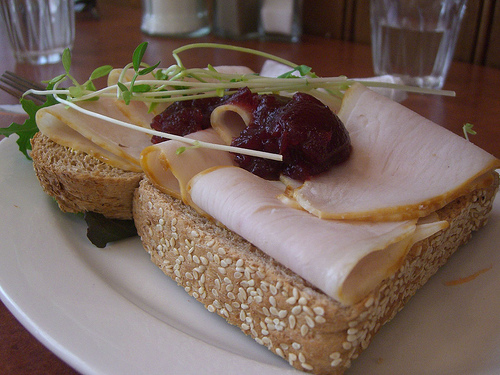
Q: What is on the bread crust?
A: Sesame seeds.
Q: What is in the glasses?
A: Water.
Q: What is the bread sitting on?
A: White plate.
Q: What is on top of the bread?
A: Lunch meat.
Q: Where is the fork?
A: Behind the plate.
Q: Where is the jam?
A: On top of lunch meat.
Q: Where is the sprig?
A: On top of jam.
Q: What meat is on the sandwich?
A: Turkey.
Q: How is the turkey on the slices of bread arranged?
A: Folded.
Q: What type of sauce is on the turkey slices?
A: Cranberry.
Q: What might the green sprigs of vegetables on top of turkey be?
A: Watercrest.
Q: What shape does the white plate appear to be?
A: Oval.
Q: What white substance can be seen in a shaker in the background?
A: Salt.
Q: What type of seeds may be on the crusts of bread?
A: Sesame.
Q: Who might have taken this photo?
A: Food photographer.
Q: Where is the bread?
A: Underneath the meat.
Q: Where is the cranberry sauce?
A: On top of the lunchmeat.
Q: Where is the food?
A: On the plate.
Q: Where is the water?
A: In the cup.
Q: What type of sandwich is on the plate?
A: Meat with cranberry.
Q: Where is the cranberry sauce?
A: In the middle.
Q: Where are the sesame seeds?
A: On the bread.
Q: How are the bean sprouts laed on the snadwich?
A: Acorss the top.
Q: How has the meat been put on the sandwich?
A: Folded.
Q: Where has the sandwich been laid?
A: On a plate.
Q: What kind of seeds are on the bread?
A: Sesame.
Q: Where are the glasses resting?
A: A table.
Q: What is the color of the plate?
A: White.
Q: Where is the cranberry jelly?
A: On the turkey.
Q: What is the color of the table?
A: Brown.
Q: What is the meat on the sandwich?
A: Turkey.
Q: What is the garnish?
A: Alfalfa.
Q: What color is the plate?
A: White.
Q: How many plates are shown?
A: One.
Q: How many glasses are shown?
A: Two.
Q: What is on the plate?
A: Sandwich.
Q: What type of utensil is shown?
A: Fork.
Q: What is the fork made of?
A: Metal.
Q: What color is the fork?
A: Silver.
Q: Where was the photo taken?
A: At lunch on the table.